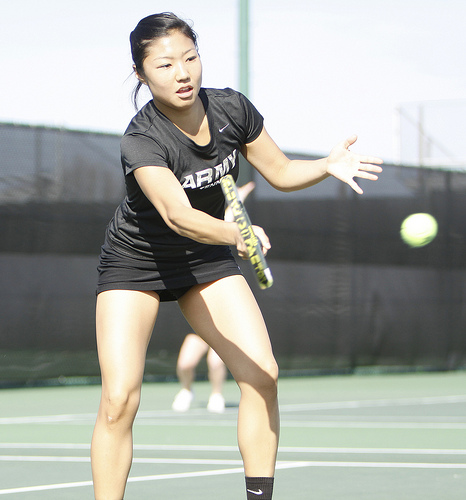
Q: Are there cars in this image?
A: No, there are no cars.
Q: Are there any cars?
A: No, there are no cars.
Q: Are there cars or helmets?
A: No, there are no cars or helmets.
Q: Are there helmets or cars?
A: No, there are no cars or helmets.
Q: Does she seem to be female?
A: Yes, the person is female.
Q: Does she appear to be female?
A: Yes, the person is female.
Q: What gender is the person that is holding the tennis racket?
A: The person is female.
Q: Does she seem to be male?
A: No, the person is female.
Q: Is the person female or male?
A: The person is female.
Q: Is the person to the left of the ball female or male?
A: The person is female.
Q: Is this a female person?
A: Yes, this is a female person.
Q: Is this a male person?
A: No, this is a female person.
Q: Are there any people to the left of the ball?
A: Yes, there is a person to the left of the ball.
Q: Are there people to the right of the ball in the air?
A: No, the person is to the left of the ball.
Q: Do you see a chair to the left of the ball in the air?
A: No, there is a person to the left of the ball.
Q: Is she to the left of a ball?
A: Yes, the person is to the left of a ball.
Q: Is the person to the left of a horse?
A: No, the person is to the left of a ball.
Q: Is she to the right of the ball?
A: No, the person is to the left of the ball.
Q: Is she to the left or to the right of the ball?
A: The person is to the left of the ball.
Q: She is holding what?
A: The person is holding the tennis racket.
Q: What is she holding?
A: The person is holding the tennis racket.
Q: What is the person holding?
A: The person is holding the tennis racket.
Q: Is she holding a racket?
A: Yes, the person is holding a racket.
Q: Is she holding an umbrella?
A: No, the person is holding a racket.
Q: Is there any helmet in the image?
A: No, there are no helmets.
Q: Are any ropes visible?
A: No, there are no ropes.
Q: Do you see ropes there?
A: No, there are no ropes.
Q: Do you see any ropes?
A: No, there are no ropes.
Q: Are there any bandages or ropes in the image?
A: No, there are no ropes or bandages.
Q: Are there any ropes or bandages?
A: No, there are no ropes or bandages.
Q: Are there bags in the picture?
A: No, there are no bags.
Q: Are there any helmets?
A: No, there are no helmets.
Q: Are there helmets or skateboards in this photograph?
A: No, there are no helmets or skateboards.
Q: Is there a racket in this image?
A: Yes, there is a racket.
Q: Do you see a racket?
A: Yes, there is a racket.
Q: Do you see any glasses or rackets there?
A: Yes, there is a racket.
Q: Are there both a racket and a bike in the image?
A: No, there is a racket but no bikes.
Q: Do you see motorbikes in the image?
A: No, there are no motorbikes.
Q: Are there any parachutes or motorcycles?
A: No, there are no motorcycles or parachutes.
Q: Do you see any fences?
A: Yes, there is a fence.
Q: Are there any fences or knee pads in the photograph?
A: Yes, there is a fence.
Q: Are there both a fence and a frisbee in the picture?
A: No, there is a fence but no frisbees.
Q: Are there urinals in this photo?
A: No, there are no urinals.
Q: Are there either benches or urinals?
A: No, there are no urinals or benches.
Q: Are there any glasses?
A: No, there are no glasses.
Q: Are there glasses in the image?
A: No, there are no glasses.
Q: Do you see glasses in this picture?
A: No, there are no glasses.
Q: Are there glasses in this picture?
A: No, there are no glasses.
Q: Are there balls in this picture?
A: Yes, there is a ball.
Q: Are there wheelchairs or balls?
A: Yes, there is a ball.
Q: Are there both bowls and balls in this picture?
A: No, there is a ball but no bowls.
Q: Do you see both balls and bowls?
A: No, there is a ball but no bowls.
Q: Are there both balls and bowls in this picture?
A: No, there is a ball but no bowls.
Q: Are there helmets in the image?
A: No, there are no helmets.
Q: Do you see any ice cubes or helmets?
A: No, there are no helmets or ice cubes.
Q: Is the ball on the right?
A: Yes, the ball is on the right of the image.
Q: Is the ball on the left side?
A: No, the ball is on the right of the image.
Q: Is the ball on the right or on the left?
A: The ball is on the right of the image.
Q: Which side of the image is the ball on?
A: The ball is on the right of the image.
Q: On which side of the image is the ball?
A: The ball is on the right of the image.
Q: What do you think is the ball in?
A: The ball is in the air.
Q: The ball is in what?
A: The ball is in the air.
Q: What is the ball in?
A: The ball is in the air.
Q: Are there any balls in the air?
A: Yes, there is a ball in the air.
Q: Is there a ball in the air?
A: Yes, there is a ball in the air.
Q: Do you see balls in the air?
A: Yes, there is a ball in the air.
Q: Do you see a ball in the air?
A: Yes, there is a ball in the air.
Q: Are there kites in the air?
A: No, there is a ball in the air.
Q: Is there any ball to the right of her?
A: Yes, there is a ball to the right of the person.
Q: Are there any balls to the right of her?
A: Yes, there is a ball to the right of the person.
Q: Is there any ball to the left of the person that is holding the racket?
A: No, the ball is to the right of the person.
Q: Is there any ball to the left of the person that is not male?
A: No, the ball is to the right of the person.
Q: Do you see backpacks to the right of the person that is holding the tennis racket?
A: No, there is a ball to the right of the person.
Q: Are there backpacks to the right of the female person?
A: No, there is a ball to the right of the person.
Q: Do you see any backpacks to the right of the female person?
A: No, there is a ball to the right of the person.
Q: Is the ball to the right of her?
A: Yes, the ball is to the right of a person.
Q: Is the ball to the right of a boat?
A: No, the ball is to the right of a person.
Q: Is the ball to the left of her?
A: No, the ball is to the right of a person.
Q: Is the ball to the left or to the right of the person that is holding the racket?
A: The ball is to the right of the person.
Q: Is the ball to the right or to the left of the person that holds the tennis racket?
A: The ball is to the right of the person.